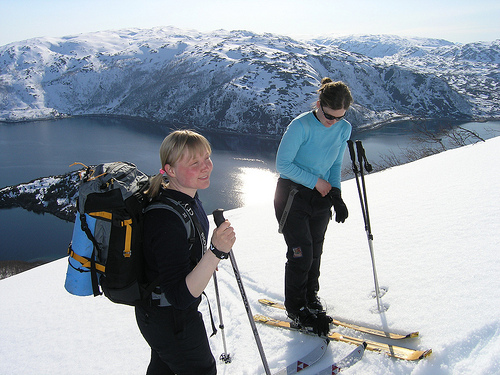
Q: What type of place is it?
A: It is a lake.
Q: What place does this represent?
A: It represents the lake.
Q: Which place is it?
A: It is a lake.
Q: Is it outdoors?
A: Yes, it is outdoors.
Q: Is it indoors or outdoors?
A: It is outdoors.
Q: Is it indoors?
A: No, it is outdoors.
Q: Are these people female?
A: Yes, all the people are female.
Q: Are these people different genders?
A: No, all the people are female.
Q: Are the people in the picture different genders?
A: No, all the people are female.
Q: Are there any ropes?
A: No, there are no ropes.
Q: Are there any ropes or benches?
A: No, there are no ropes or benches.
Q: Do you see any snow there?
A: Yes, there is snow.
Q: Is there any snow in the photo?
A: Yes, there is snow.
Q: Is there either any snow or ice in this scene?
A: Yes, there is snow.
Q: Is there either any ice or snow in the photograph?
A: Yes, there is snow.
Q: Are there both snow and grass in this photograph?
A: No, there is snow but no grass.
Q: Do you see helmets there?
A: No, there are no helmets.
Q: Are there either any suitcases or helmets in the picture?
A: No, there are no helmets or suitcases.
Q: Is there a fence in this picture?
A: No, there are no fences.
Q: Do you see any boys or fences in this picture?
A: No, there are no fences or boys.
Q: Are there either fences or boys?
A: No, there are no fences or boys.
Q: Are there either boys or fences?
A: No, there are no fences or boys.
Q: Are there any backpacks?
A: Yes, there is a backpack.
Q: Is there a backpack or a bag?
A: Yes, there is a backpack.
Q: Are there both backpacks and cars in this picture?
A: No, there is a backpack but no cars.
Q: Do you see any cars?
A: No, there are no cars.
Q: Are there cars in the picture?
A: No, there are no cars.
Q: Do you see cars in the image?
A: No, there are no cars.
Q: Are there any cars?
A: No, there are no cars.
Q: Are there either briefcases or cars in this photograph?
A: No, there are no cars or briefcases.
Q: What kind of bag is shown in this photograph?
A: The bag is a backpack.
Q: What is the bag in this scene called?
A: The bag is a backpack.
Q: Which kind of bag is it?
A: The bag is a backpack.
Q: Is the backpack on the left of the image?
A: Yes, the backpack is on the left of the image.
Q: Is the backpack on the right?
A: No, the backpack is on the left of the image.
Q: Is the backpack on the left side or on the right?
A: The backpack is on the left of the image.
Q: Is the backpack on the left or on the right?
A: The backpack is on the left of the image.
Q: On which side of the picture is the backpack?
A: The backpack is on the left of the image.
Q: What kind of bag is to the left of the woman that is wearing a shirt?
A: The bag is a backpack.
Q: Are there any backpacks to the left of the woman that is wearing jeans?
A: Yes, there is a backpack to the left of the woman.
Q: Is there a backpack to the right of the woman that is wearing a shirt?
A: No, the backpack is to the left of the woman.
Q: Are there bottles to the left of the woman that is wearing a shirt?
A: No, there is a backpack to the left of the woman.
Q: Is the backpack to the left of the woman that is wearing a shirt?
A: Yes, the backpack is to the left of the woman.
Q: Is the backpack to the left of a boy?
A: No, the backpack is to the left of the woman.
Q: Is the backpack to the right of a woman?
A: No, the backpack is to the left of a woman.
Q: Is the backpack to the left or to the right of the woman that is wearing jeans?
A: The backpack is to the left of the woman.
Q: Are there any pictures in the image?
A: No, there are no pictures.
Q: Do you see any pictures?
A: No, there are no pictures.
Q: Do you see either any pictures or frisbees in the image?
A: No, there are no pictures or frisbees.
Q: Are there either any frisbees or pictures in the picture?
A: No, there are no pictures or frisbees.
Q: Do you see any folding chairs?
A: No, there are no folding chairs.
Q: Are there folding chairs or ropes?
A: No, there are no folding chairs or ropes.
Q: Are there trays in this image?
A: No, there are no trays.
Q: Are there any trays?
A: No, there are no trays.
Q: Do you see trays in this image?
A: No, there are no trays.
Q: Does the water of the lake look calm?
A: Yes, the water is calm.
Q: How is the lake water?
A: The water is calm.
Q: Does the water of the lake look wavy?
A: No, the water is calm.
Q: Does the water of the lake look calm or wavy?
A: The water is calm.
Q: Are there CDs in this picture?
A: No, there are no cds.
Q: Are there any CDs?
A: No, there are no cds.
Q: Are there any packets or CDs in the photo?
A: No, there are no CDs or packets.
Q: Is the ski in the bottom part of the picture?
A: Yes, the ski is in the bottom of the image.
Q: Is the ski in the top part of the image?
A: No, the ski is in the bottom of the image.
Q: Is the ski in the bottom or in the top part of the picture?
A: The ski is in the bottom of the image.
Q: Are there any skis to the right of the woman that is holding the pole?
A: Yes, there is a ski to the right of the woman.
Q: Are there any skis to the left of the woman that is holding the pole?
A: No, the ski is to the right of the woman.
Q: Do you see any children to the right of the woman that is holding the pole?
A: No, there is a ski to the right of the woman.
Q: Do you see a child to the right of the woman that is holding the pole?
A: No, there is a ski to the right of the woman.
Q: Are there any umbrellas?
A: No, there are no umbrellas.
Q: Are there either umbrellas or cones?
A: No, there are no umbrellas or cones.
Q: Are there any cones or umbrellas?
A: No, there are no umbrellas or cones.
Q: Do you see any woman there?
A: Yes, there is a woman.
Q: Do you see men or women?
A: Yes, there is a woman.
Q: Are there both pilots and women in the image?
A: No, there is a woman but no pilots.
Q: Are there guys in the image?
A: No, there are no guys.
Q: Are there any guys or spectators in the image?
A: No, there are no guys or spectators.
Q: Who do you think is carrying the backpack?
A: The woman is carrying the backpack.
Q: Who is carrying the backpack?
A: The woman is carrying the backpack.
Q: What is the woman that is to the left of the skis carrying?
A: The woman is carrying a backpack.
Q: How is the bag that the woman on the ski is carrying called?
A: The bag is a backpack.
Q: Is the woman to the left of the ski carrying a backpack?
A: Yes, the woman is carrying a backpack.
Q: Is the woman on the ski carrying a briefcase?
A: No, the woman is carrying a backpack.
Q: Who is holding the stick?
A: The woman is holding the stick.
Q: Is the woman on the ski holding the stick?
A: Yes, the woman is holding the stick.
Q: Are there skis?
A: Yes, there are skis.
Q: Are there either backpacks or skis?
A: Yes, there are skis.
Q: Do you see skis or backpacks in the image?
A: Yes, there are skis.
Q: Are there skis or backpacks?
A: Yes, there are skis.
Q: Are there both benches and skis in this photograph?
A: No, there are skis but no benches.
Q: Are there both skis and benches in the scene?
A: No, there are skis but no benches.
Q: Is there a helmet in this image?
A: No, there are no helmets.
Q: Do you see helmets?
A: No, there are no helmets.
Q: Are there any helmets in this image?
A: No, there are no helmets.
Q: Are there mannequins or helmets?
A: No, there are no helmets or mannequins.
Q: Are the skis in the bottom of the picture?
A: Yes, the skis are in the bottom of the image.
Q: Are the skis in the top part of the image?
A: No, the skis are in the bottom of the image.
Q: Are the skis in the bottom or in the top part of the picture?
A: The skis are in the bottom of the image.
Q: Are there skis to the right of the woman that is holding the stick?
A: Yes, there are skis to the right of the woman.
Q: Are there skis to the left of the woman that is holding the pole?
A: No, the skis are to the right of the woman.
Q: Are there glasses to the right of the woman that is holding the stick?
A: No, there are skis to the right of the woman.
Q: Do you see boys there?
A: No, there are no boys.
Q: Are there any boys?
A: No, there are no boys.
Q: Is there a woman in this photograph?
A: Yes, there is a woman.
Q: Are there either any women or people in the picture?
A: Yes, there is a woman.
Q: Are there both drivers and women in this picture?
A: No, there is a woman but no drivers.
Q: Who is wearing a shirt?
A: The woman is wearing a shirt.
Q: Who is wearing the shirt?
A: The woman is wearing a shirt.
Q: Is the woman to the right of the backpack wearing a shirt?
A: Yes, the woman is wearing a shirt.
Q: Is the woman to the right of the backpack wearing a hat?
A: No, the woman is wearing a shirt.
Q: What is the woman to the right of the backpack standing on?
A: The woman is standing on the ski.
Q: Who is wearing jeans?
A: The woman is wearing jeans.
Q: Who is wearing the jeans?
A: The woman is wearing jeans.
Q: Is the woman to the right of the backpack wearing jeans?
A: Yes, the woman is wearing jeans.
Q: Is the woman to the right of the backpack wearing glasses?
A: No, the woman is wearing jeans.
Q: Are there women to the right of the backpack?
A: Yes, there is a woman to the right of the backpack.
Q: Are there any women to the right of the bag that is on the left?
A: Yes, there is a woman to the right of the backpack.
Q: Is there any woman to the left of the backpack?
A: No, the woman is to the right of the backpack.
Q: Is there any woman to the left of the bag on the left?
A: No, the woman is to the right of the backpack.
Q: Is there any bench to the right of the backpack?
A: No, there is a woman to the right of the backpack.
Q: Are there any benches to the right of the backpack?
A: No, there is a woman to the right of the backpack.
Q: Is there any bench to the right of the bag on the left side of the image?
A: No, there is a woman to the right of the backpack.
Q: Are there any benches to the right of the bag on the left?
A: No, there is a woman to the right of the backpack.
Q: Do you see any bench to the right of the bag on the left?
A: No, there is a woman to the right of the backpack.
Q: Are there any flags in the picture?
A: No, there are no flags.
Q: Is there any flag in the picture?
A: No, there are no flags.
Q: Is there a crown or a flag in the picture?
A: No, there are no flags or crowns.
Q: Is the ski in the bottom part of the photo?
A: Yes, the ski is in the bottom of the image.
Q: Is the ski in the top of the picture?
A: No, the ski is in the bottom of the image.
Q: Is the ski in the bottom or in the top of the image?
A: The ski is in the bottom of the image.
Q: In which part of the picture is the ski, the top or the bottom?
A: The ski is in the bottom of the image.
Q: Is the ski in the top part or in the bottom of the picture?
A: The ski is in the bottom of the image.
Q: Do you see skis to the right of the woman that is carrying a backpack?
A: Yes, there is a ski to the right of the woman.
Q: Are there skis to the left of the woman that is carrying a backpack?
A: No, the ski is to the right of the woman.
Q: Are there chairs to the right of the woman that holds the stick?
A: No, there is a ski to the right of the woman.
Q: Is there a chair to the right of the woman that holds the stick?
A: No, there is a ski to the right of the woman.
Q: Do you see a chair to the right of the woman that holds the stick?
A: No, there is a ski to the right of the woman.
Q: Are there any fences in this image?
A: No, there are no fences.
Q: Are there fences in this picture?
A: No, there are no fences.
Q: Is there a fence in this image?
A: No, there are no fences.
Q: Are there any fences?
A: No, there are no fences.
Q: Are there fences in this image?
A: No, there are no fences.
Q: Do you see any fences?
A: No, there are no fences.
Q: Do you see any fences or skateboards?
A: No, there are no fences or skateboards.